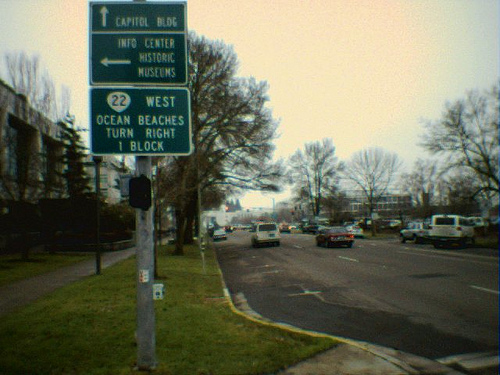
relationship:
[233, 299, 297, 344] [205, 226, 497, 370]
curb next to street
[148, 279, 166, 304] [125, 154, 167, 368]
attachment on pole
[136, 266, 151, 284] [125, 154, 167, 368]
attachment on pole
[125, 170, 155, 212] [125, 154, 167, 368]
attachment on pole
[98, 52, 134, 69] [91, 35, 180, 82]
white arrow on a green background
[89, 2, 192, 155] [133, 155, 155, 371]
sign on a pole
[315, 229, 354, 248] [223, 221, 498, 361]
car driving down road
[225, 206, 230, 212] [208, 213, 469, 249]
light near cars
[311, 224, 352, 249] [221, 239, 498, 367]
car on pavement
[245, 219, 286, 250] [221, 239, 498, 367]
car on pavement